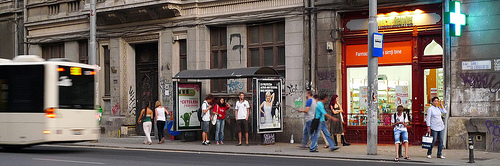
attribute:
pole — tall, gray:
[366, 0, 377, 156]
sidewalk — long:
[32, 137, 497, 163]